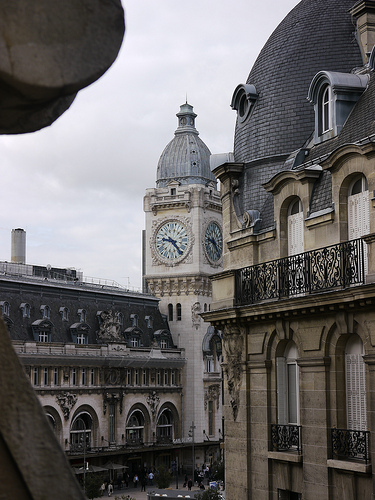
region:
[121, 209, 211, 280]
the clock on a building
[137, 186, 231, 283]
a big clock on a building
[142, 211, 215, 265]
a big clock on a building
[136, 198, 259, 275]
a clock on a building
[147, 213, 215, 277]
a clock on a building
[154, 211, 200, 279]
clock on top of the tower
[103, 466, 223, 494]
people walking in the courtyard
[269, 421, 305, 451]
metal railing on the outside of the window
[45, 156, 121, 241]
clouds covering the blue sky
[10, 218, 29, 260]
smoke stack behind the building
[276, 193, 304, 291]
arched windows in the top of the building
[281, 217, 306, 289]
white shutters on the windows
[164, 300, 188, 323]
arched windows on the tower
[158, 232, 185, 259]
black hands on the clock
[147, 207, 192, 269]
time on the clock is 9:25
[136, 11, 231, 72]
The sky is cloudy.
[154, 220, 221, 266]
Two clocks are on the building.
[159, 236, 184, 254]
The clock reads 9:20.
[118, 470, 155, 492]
People are on the street below.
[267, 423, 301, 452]
A railing is on the building.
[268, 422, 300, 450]
The railing is black.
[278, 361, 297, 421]
The window is white.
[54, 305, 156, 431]
The building is ornately designed.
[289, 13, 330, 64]
The dome is made of bricks.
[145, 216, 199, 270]
The clock on top of the wall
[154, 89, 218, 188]
The top of the building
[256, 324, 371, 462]
The windows on the side of the building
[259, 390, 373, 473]
The balcony on the side of the building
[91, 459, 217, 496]
The people on the sidewalk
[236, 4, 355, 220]
The roof of the building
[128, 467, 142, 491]
The man is wearing a brown jacket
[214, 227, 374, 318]
The top balcony of the building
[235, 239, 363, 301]
The gate is made of iron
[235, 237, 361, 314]
The color of the gate is black